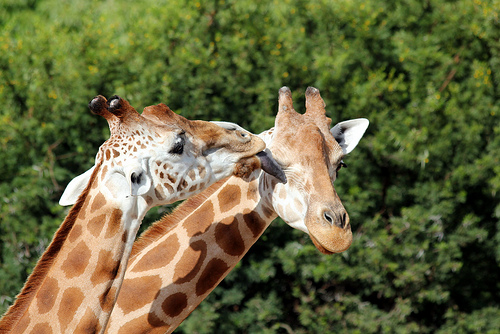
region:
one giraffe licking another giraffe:
[71, 35, 483, 317]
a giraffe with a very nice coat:
[65, 89, 230, 257]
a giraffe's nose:
[309, 208, 369, 262]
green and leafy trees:
[360, 27, 478, 309]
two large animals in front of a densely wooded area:
[18, 11, 463, 302]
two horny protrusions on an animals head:
[84, 73, 134, 130]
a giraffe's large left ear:
[327, 102, 389, 179]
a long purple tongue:
[251, 128, 285, 201]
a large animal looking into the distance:
[247, 76, 414, 328]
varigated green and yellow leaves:
[18, 9, 238, 71]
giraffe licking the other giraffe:
[3, 90, 275, 327]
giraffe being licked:
[70, 77, 375, 332]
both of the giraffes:
[1, 77, 383, 331]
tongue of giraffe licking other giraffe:
[230, 137, 302, 194]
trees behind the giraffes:
[1, 1, 498, 104]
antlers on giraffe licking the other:
[75, 89, 157, 135]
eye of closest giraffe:
[149, 125, 209, 172]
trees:
[6, 0, 493, 95]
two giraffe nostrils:
[315, 204, 360, 241]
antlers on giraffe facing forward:
[248, 71, 375, 153]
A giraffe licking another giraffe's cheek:
[204, 118, 307, 195]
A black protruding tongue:
[251, 147, 302, 183]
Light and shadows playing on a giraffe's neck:
[148, 154, 295, 332]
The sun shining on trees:
[4, 11, 185, 61]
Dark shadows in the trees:
[430, 210, 492, 313]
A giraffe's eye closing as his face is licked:
[268, 151, 302, 179]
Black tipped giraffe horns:
[85, 93, 145, 129]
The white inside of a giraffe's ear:
[324, 111, 374, 157]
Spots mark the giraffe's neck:
[34, 195, 152, 313]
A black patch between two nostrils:
[321, 205, 351, 230]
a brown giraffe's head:
[80, 87, 260, 219]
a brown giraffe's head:
[231, 76, 369, 269]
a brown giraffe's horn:
[105, 93, 140, 120]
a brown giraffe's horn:
[89, 92, 114, 123]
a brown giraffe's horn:
[272, 84, 294, 121]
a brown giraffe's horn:
[302, 83, 324, 120]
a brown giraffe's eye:
[168, 135, 188, 160]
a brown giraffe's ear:
[333, 117, 369, 149]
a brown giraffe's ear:
[113, 155, 154, 205]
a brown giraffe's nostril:
[322, 210, 334, 225]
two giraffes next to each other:
[0, 74, 376, 332]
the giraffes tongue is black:
[257, 147, 287, 191]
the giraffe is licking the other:
[228, 117, 311, 221]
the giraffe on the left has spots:
[0, 67, 267, 332]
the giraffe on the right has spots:
[87, 74, 381, 331]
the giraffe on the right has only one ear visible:
[318, 108, 380, 164]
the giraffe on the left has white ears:
[50, 155, 159, 218]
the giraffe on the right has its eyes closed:
[261, 131, 347, 185]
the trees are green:
[1, 0, 498, 332]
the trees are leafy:
[0, 0, 499, 330]